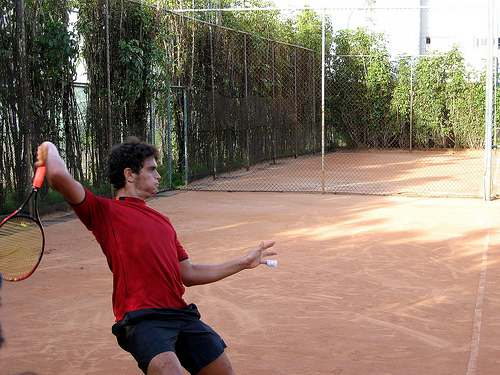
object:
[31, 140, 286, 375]
man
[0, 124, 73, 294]
tennis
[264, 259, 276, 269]
band-aid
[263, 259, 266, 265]
finger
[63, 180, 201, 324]
shirt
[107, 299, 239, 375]
shorts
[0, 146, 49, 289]
tennis racket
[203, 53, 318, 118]
fence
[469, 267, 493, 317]
line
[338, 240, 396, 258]
floor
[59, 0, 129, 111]
splint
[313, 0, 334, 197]
pole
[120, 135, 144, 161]
hair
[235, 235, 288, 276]
hand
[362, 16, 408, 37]
sky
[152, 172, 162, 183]
nose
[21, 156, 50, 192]
handle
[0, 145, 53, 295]
racket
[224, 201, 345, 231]
court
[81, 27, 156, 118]
trees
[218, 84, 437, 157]
net